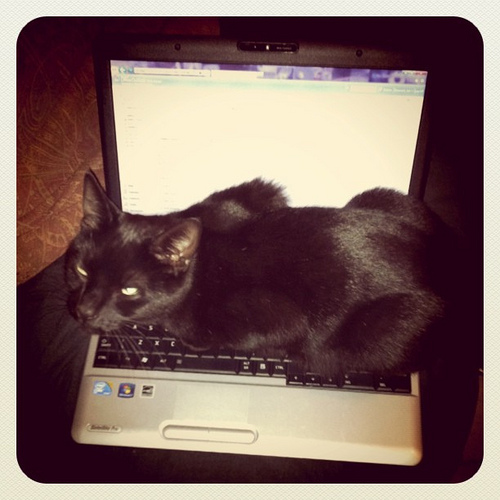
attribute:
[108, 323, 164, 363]
keys — black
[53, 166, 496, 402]
cat — black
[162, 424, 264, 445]
button — mouse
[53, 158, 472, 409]
cat — black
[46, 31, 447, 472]
computer — laptop, open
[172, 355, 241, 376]
bar — space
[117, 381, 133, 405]
logo — Microsoft Windows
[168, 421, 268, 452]
button — track pad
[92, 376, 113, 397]
sticker — Intel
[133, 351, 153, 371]
key — black, Windows Logo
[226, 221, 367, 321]
fur — black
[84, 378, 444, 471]
laptop —  gray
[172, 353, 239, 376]
key — small, black, space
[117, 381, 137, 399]
sticker — Microsoft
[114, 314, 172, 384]
whiskers — white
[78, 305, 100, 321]
nose — black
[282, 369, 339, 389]
keys — bottom, arrows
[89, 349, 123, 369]
key — black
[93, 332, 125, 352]
key — black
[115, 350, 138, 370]
key — black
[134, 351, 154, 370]
key — black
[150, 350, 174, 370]
key — black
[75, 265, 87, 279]
eye — partially closed, green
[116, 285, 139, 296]
eye — partially closed, green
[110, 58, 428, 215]
screen — on, glowing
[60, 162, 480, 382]
fur — black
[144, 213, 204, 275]
ear — perked up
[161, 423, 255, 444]
button — oblong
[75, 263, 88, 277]
eye — narrow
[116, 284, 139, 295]
eye — narrow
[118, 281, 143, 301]
eye — yellow